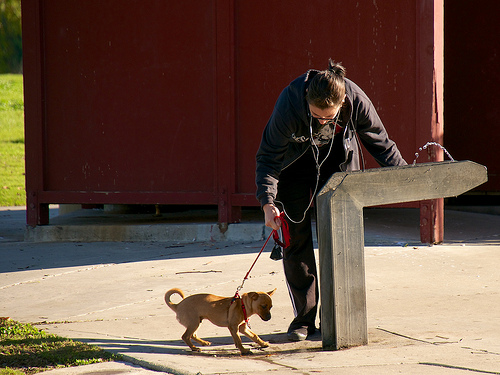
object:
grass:
[0, 317, 123, 373]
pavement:
[0, 205, 500, 373]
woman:
[256, 56, 410, 337]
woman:
[253, 77, 367, 288]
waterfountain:
[307, 152, 492, 330]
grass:
[1, 90, 28, 195]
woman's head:
[306, 55, 347, 123]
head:
[307, 57, 347, 124]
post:
[313, 156, 489, 354]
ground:
[372, 96, 442, 149]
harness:
[234, 269, 256, 321]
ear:
[249, 292, 259, 301]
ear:
[264, 287, 276, 295]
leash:
[224, 209, 292, 329]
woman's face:
[306, 101, 343, 131]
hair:
[303, 57, 346, 110]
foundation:
[30, 220, 320, 247]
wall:
[41, 1, 424, 208]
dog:
[155, 286, 280, 358]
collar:
[235, 298, 252, 323]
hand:
[262, 197, 283, 232]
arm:
[257, 93, 295, 206]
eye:
[326, 112, 335, 119]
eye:
[309, 111, 319, 117]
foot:
[285, 314, 315, 343]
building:
[21, 17, 451, 243]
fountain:
[413, 137, 458, 165]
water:
[423, 135, 461, 161]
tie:
[266, 216, 287, 240]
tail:
[163, 288, 180, 308]